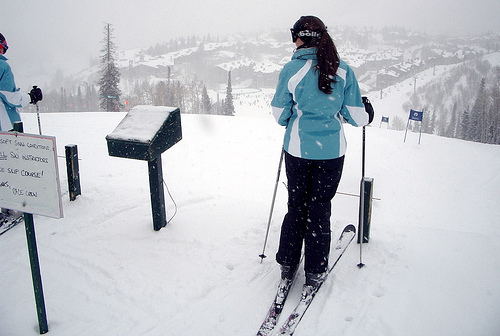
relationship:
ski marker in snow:
[404, 108, 426, 144] [1, 111, 500, 335]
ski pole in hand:
[356, 96, 368, 270] [362, 98, 374, 124]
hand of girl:
[362, 98, 374, 124] [271, 16, 373, 286]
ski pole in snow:
[356, 96, 368, 270] [1, 111, 500, 335]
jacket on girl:
[272, 48, 369, 160] [271, 16, 373, 286]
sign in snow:
[0, 133, 64, 335] [1, 111, 500, 335]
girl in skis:
[271, 16, 373, 286] [257, 223, 356, 335]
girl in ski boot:
[271, 16, 373, 286] [305, 256, 328, 288]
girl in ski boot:
[271, 16, 373, 286] [280, 253, 301, 282]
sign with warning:
[0, 133, 64, 335] [0, 132, 63, 216]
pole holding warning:
[25, 214, 49, 336] [0, 132, 63, 216]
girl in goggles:
[271, 16, 373, 286] [291, 29, 325, 43]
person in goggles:
[0, 33, 43, 234] [0, 40, 10, 53]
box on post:
[106, 105, 181, 231] [148, 151, 167, 231]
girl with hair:
[271, 16, 373, 286] [294, 15, 339, 93]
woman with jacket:
[271, 16, 373, 286] [272, 48, 369, 160]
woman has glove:
[271, 16, 373, 286] [29, 87, 44, 104]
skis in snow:
[257, 223, 356, 335] [1, 111, 500, 335]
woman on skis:
[271, 16, 373, 286] [257, 223, 356, 335]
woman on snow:
[271, 16, 373, 286] [1, 111, 500, 335]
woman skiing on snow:
[271, 16, 373, 286] [1, 111, 500, 335]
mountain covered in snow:
[15, 33, 500, 145] [1, 111, 500, 335]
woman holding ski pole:
[0, 33, 43, 234] [356, 96, 368, 270]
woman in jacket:
[271, 16, 373, 286] [272, 48, 369, 160]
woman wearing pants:
[271, 16, 373, 286] [276, 151, 345, 273]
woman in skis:
[271, 16, 373, 286] [257, 223, 356, 335]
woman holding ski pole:
[271, 16, 373, 286] [356, 96, 368, 270]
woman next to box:
[271, 16, 373, 286] [106, 105, 181, 231]